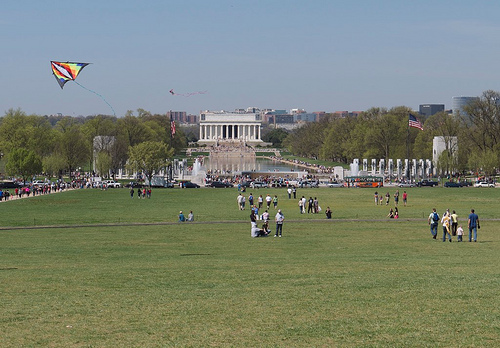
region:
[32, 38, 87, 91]
Colorful kite with blue, red, and green spots being flown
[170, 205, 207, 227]
Two people wearing a blue and white shirt sitting down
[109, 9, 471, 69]
Mostly clear blue sky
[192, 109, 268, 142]
White building supported by large white columns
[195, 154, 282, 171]
Long water feature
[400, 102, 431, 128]
Waving flag of the United States of America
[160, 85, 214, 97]
Kite flying in the distance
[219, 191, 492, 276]
People walking through the grassy field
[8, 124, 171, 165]
Stand of green trees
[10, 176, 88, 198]
Line of people walking together on a white path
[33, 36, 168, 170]
a rainbow patterned kite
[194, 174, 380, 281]
people on a grassy lawn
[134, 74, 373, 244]
the national mall in dc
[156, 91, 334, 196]
looking at the lincoln memorial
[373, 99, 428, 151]
an american flag flying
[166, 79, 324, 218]
the fountains are spraying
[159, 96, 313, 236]
people at the lincoln memorial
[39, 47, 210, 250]
flying a kite at the park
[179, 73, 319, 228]
the memorial is white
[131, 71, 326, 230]
trees on either side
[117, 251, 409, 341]
The grass is green.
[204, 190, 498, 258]
A lot of people are on the grass.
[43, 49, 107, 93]
A kite is flying.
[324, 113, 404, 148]
Trees are in the background.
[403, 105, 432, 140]
A flag is in the background.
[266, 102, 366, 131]
A city sky line is in the background.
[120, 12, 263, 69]
The sky is blue.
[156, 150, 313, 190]
A pool of water.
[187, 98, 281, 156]
A famous landmark.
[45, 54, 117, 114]
A kite in the air.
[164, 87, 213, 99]
A kite in the air.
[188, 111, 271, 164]
Capitol building with crowd.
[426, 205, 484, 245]
A group of people walking.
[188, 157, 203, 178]
A fountain sprays water.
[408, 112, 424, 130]
The american flag.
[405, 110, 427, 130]
The flag is waving.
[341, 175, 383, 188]
A bus park in the line.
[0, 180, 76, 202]
A crowd walks on the sidewalk.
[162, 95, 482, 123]
High rises in the distance.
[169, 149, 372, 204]
people in front of pond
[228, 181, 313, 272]
people standing on grass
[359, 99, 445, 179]
flag flying by fountain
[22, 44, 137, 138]
flag flying in sky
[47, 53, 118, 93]
blue, red, yellow, and white kite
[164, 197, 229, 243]
people sitting on grass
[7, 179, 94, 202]
people walking on path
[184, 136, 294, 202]
reflection of building in water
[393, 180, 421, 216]
person wearing red shirt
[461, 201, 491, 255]
person wearing blue shirt